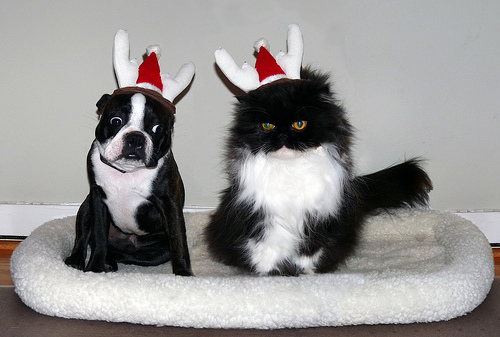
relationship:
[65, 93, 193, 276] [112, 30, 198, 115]
animal wearing antlers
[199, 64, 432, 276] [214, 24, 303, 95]
animal wearing antlers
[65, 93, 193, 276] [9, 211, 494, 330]
animal sitting on bed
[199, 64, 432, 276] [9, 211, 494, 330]
animal sitting on bed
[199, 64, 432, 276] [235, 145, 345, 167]
animal has neck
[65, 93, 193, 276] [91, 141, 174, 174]
animal has neck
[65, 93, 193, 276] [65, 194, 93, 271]
animal has leg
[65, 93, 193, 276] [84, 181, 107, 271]
animal has leg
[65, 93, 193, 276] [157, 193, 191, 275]
animal has leg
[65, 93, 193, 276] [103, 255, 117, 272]
animal has leg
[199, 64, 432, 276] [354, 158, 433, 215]
animal has tail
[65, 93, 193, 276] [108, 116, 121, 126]
animal has eye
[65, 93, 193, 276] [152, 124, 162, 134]
animal has eye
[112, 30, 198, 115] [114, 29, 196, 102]
antlers has antlers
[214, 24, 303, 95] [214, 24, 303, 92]
antlers has antlers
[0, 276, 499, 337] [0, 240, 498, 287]
rug on top of ground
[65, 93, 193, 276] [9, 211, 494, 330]
animal on top of bed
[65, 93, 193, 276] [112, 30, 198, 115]
animal has antlers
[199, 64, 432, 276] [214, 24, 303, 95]
animal has antlers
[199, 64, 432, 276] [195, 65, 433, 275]
animal has fur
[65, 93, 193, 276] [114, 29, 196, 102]
animal has antlers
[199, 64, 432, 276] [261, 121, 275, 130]
animal has eye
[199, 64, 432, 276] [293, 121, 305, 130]
animal has eye